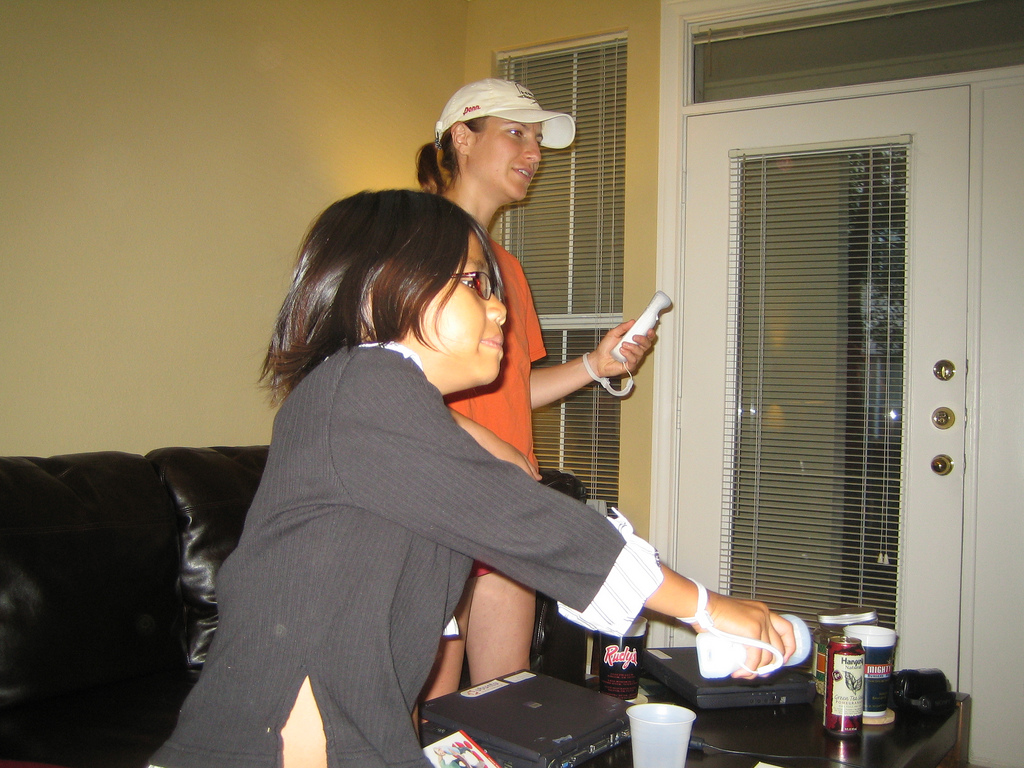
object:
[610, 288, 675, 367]
wii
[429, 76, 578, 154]
hat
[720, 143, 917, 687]
blinds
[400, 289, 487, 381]
cheek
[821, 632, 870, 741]
can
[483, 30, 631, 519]
blinds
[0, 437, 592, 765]
couch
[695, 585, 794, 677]
girls hand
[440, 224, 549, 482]
woman shirt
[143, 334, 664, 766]
woman shirt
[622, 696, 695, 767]
cup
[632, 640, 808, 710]
laptop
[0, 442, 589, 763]
sofa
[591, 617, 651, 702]
cup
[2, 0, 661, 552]
wall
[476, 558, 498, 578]
shorts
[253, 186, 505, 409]
hair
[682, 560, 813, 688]
strap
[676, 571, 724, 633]
wrist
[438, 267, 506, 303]
glasses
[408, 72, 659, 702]
woman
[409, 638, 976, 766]
table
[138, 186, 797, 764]
woman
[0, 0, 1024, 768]
building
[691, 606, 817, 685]
wii